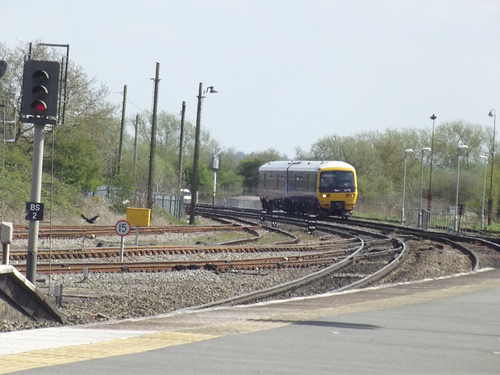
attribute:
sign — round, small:
[117, 222, 135, 235]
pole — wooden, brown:
[190, 83, 207, 222]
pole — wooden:
[179, 101, 186, 223]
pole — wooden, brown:
[146, 63, 157, 209]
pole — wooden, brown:
[131, 116, 145, 174]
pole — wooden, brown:
[114, 85, 126, 181]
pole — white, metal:
[399, 147, 413, 225]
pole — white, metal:
[417, 146, 431, 225]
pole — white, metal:
[450, 144, 464, 235]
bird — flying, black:
[77, 208, 102, 225]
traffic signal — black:
[17, 56, 60, 132]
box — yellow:
[124, 206, 152, 231]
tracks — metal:
[37, 214, 462, 289]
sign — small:
[27, 200, 47, 223]